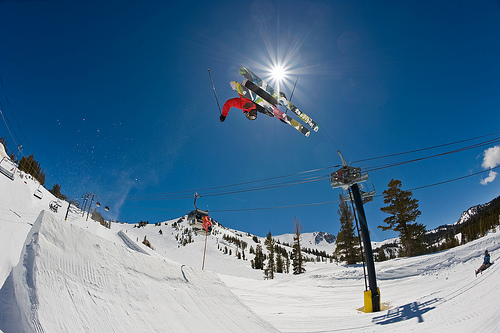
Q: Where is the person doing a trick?
A: In the air.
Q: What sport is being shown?
A: Skiing.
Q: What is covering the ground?
A: Snow.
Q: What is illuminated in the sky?
A: Sun.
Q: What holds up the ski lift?
A: Wires.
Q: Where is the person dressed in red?
A: In the air.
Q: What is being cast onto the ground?
A: Shadows.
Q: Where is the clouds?
A: Right side of the image.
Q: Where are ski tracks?
A: In the snow.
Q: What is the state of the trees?
A: Green.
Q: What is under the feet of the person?
A: Skis.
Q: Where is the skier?
A: In the sky.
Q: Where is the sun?
A: Behind the skier.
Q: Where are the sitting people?
A: On the ski lift.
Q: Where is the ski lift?
A: Behind the skier.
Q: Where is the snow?
A: On the ground.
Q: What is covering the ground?
A: Snow.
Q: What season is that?
A: Winter.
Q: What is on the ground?
A: Snow.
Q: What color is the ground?
A: White.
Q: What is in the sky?
A: Clouds.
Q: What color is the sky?
A: Blue.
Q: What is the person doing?
A: Skiing.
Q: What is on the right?
A: Chair lift.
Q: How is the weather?
A: Cold.